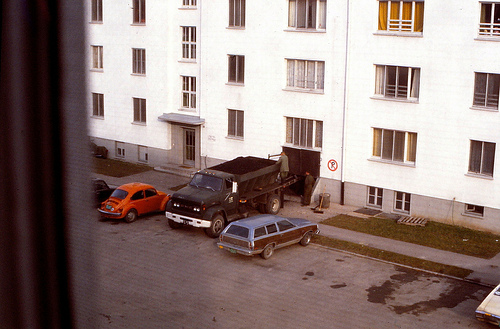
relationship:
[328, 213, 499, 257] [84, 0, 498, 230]
grass front of building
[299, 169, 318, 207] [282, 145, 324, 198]
man in front entrance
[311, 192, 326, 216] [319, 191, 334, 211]
broom leaning on barrel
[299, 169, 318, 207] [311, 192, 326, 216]
man near broom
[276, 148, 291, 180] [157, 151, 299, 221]
man on top truck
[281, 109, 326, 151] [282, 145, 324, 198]
window above entrance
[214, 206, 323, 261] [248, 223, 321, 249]
automobile with brown  panels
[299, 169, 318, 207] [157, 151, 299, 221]
man on  back delivery truck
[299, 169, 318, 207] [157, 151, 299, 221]
man on side of truck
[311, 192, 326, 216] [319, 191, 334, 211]
broom propped on trashcan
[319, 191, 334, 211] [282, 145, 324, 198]
trashcan beside entrance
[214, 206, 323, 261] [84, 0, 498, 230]
automobile in front of building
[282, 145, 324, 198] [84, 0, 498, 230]
door on building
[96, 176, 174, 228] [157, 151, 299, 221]
car parked next to truck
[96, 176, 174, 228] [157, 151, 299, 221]
car next to truck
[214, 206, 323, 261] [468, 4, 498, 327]
car parked to right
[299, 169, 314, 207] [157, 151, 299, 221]
man unloading truck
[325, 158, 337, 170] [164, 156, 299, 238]
sign in front of truck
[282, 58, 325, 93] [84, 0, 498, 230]
window on building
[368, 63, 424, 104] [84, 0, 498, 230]
window on building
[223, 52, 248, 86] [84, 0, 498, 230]
window on building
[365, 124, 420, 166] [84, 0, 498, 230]
window on building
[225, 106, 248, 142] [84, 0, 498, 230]
window on building